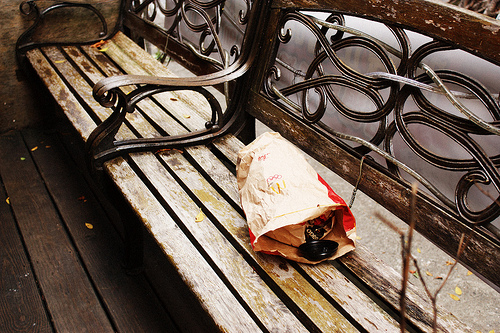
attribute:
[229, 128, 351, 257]
bag — brown, trash, paper, mcdonalds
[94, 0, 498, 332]
bench — old, wooden, peeling, wood, metal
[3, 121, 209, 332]
porch — wooden, wood, dark brown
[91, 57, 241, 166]
arm — metal, black, brass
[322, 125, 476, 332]
twigs — small, thin, brown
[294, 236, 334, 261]
coffee lid — plastic, black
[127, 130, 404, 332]
slats — wooden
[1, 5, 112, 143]
wall — brick, stone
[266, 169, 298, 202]
logo — mcdonalds, yellow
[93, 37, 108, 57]
leaf — red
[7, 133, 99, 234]
leaves — multicolored, small, yellow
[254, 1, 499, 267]
back — iron, metal, designed, abstract, decorative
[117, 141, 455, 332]
seat — wood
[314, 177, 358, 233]
sign — red